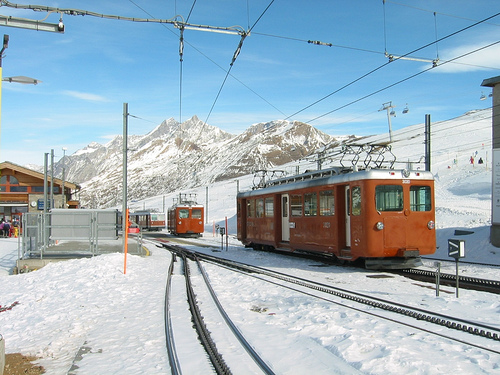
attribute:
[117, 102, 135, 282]
pole — large, silver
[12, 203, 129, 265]
enclosure — clear, chain link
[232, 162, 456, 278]
train — electric, large, brown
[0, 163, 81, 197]
roof — slanted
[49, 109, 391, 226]
mountain range — covered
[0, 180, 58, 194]
windows — clear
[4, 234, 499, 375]
tracks — white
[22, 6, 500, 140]
wires — above, electric, connecting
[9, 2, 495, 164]
sky — blue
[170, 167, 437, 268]
train car — electric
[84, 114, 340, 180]
mountains — tall